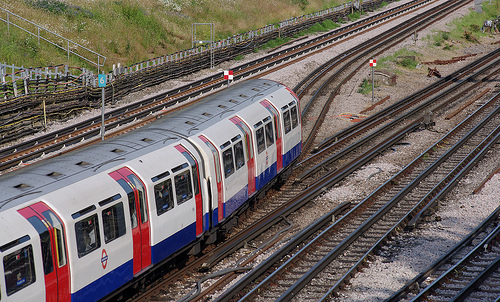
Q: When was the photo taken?
A: During the day.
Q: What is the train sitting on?
A: The track.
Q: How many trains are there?
A: One.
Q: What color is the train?
A: Grey, white and blue.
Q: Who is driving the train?
A: The conductor.